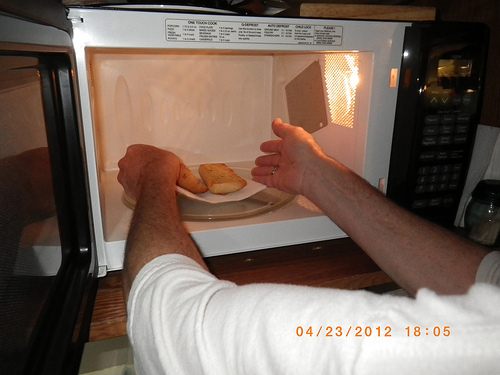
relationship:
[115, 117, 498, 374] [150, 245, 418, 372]
man wear shirt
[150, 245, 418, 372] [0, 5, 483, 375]
shirt reaching inside of black microwave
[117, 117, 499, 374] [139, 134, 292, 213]
man holding food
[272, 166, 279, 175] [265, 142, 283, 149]
ring on finger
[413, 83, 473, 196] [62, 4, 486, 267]
buttons on microwave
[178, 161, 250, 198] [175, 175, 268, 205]
food on napkin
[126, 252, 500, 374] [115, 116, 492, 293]
sleeve over arms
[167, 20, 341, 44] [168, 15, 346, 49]
words on label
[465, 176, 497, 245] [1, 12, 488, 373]
jar to side of microwave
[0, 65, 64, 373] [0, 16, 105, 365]
window on door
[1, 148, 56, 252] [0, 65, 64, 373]
reflection on window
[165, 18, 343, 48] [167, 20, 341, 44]
words on words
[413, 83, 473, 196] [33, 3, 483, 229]
buttons on microwave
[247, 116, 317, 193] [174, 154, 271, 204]
hand on paper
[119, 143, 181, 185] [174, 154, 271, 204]
hand on paper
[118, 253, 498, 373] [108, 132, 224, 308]
sleeve on arm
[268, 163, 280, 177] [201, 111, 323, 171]
ring on finger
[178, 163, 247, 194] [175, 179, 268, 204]
food on napkin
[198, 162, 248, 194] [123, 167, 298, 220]
hot pocket on glass plate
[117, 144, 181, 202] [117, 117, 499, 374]
hand on man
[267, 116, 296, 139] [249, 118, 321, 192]
finger on hand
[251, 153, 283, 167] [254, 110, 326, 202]
finger on hand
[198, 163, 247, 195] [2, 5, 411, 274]
hot pocket inside microwave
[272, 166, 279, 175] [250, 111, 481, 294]
ring on hand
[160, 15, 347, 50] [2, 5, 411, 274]
instruction on microwave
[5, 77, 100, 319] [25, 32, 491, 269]
glass door of microwave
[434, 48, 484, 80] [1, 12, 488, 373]
display screen on microwave